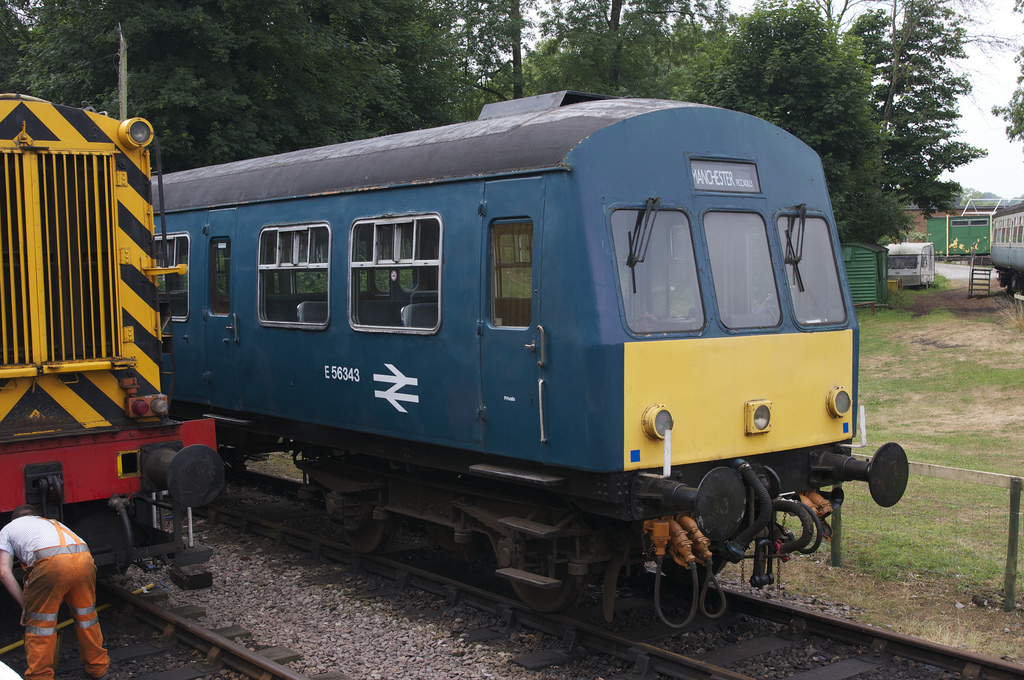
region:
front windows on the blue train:
[605, 205, 844, 354]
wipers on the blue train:
[613, 195, 810, 271]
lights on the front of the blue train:
[652, 379, 850, 456]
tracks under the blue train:
[259, 470, 914, 677]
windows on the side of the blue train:
[123, 220, 557, 319]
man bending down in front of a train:
[11, 507, 123, 667]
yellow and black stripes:
[4, 82, 198, 443]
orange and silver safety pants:
[26, 549, 106, 673]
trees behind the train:
[13, 9, 922, 213]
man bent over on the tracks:
[0, 497, 134, 675]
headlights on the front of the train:
[637, 389, 859, 438]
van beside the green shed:
[886, 228, 938, 298]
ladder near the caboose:
[953, 253, 993, 305]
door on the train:
[478, 168, 545, 448]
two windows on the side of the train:
[250, 214, 454, 341]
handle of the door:
[520, 310, 555, 372]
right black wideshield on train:
[777, 193, 828, 283]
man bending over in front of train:
[0, 491, 136, 675]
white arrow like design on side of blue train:
[359, 351, 451, 459]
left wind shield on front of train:
[599, 195, 732, 347]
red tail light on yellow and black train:
[120, 386, 156, 428]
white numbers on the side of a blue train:
[312, 354, 380, 392]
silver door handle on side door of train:
[528, 318, 561, 391]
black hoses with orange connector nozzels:
[632, 516, 737, 631]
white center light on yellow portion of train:
[727, 382, 795, 450]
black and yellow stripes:
[0, 92, 172, 440]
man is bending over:
[8, 507, 127, 676]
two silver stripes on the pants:
[17, 604, 71, 643]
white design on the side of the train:
[371, 357, 422, 412]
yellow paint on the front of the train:
[621, 323, 869, 473]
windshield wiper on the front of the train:
[625, 190, 673, 295]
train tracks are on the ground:
[144, 431, 1020, 676]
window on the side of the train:
[345, 213, 451, 328]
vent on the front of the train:
[4, 136, 137, 381]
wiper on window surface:
[610, 201, 705, 334]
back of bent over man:
[0, 508, 111, 676]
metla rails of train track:
[224, 464, 1012, 676]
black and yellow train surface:
[0, 97, 159, 445]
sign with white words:
[685, 154, 762, 194]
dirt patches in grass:
[854, 310, 1019, 582]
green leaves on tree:
[711, 9, 908, 248]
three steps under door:
[471, 175, 564, 593]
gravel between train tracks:
[151, 519, 591, 676]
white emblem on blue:
[372, 356, 421, 417]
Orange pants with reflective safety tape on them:
[17, 541, 109, 674]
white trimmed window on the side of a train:
[339, 212, 450, 336]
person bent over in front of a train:
[4, 502, 115, 671]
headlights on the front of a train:
[646, 386, 856, 438]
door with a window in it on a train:
[472, 168, 558, 463]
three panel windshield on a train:
[599, 187, 847, 331]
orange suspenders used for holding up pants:
[38, 512, 80, 547]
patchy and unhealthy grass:
[860, 303, 1022, 567]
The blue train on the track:
[147, 90, 913, 593]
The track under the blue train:
[571, 589, 1015, 676]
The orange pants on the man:
[21, 548, 113, 676]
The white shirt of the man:
[1, 517, 88, 559]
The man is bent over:
[1, 507, 115, 675]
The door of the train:
[472, 179, 552, 462]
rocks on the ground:
[322, 617, 411, 674]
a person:
[16, 521, 119, 676]